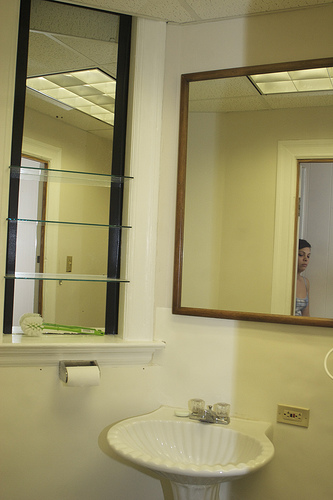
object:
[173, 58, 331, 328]
frame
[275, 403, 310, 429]
electric outlet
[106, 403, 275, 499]
sink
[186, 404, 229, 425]
faucet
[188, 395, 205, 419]
faucet handle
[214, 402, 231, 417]
faucet handle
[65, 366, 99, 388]
toilet paper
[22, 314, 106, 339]
bathroom brush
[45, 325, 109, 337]
handle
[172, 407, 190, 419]
soap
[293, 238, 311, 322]
reflection of woman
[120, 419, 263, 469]
scalloped bowl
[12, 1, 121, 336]
mirror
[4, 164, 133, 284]
shelves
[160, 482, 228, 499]
pedestal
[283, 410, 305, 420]
double socket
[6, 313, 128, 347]
shelf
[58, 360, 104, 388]
holder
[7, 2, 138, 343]
border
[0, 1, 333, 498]
bathroom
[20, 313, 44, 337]
bristles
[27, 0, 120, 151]
ceiling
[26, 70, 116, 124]
light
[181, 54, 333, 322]
mirror